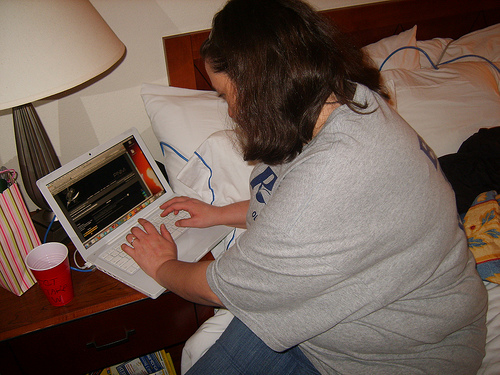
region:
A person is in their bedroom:
[26, 2, 486, 370]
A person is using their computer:
[55, 17, 475, 370]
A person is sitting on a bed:
[75, 2, 483, 372]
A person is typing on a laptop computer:
[26, 38, 478, 373]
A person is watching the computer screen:
[27, 13, 493, 360]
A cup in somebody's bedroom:
[25, 240, 70, 275]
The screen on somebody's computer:
[55, 168, 145, 218]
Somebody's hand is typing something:
[118, 217, 173, 265]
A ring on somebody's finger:
[125, 233, 140, 244]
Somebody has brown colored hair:
[150, 3, 419, 166]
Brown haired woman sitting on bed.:
[136, 0, 486, 373]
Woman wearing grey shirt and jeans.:
[120, 5, 486, 373]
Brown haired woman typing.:
[121, 0, 487, 371]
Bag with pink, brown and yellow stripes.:
[0, 165, 40, 295]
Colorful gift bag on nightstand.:
[0, 165, 43, 295]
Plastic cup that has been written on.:
[25, 240, 75, 307]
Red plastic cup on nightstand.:
[26, 238, 77, 311]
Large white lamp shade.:
[0, 0, 127, 112]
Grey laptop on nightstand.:
[35, 127, 237, 297]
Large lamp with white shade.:
[1, 3, 129, 232]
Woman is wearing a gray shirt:
[202, 75, 489, 372]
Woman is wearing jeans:
[171, 308, 338, 373]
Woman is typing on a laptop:
[31, 123, 239, 298]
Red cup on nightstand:
[22, 238, 77, 308]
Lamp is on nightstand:
[0, 0, 132, 250]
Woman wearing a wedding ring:
[125, 232, 140, 247]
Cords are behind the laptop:
[37, 207, 96, 272]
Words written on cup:
[33, 273, 75, 307]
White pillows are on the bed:
[137, 20, 495, 253]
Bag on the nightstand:
[0, 162, 51, 297]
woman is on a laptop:
[0, 3, 496, 365]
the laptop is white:
[40, 152, 226, 275]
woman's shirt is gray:
[193, 79, 483, 373]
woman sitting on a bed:
[104, 1, 493, 359]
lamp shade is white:
[0, 1, 127, 94]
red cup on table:
[14, 223, 86, 314]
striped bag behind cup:
[2, 183, 67, 308]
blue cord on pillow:
[152, 43, 494, 253]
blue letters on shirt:
[235, 163, 302, 222]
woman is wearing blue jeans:
[155, 314, 322, 370]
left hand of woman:
[102, 203, 211, 263]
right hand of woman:
[150, 181, 226, 238]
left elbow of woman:
[194, 247, 265, 312]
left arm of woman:
[107, 195, 333, 302]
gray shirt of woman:
[270, 152, 475, 334]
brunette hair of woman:
[216, 98, 334, 172]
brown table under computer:
[11, 300, 178, 335]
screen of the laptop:
[17, 148, 204, 243]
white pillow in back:
[130, 78, 227, 153]